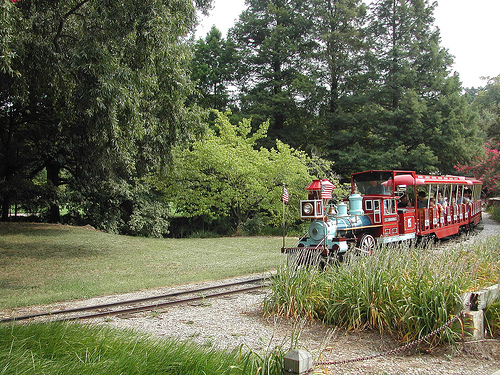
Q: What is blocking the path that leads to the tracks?
A: A metal chain.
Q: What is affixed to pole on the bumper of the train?
A: A flag.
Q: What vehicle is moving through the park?
A: A train.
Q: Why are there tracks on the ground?
A: They are for a train.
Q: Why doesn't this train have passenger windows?
A: So people can easily see their surroundings.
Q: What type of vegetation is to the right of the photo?
A: Plants.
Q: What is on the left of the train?
A: An expanse of grass.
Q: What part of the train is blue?
A: The engine.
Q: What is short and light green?
A: The tree.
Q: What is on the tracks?
A: The train.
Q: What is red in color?
A: The train.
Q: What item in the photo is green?
A: The trees.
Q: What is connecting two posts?
A: The chains.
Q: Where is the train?
A: On track.